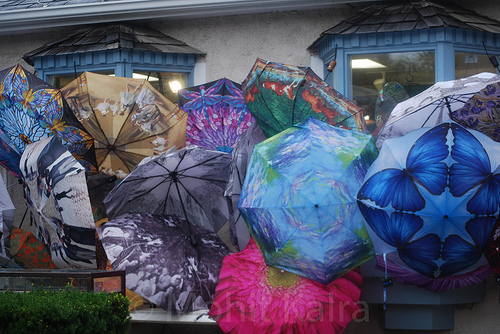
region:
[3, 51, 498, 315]
these are umbrellas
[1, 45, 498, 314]
the umbrellas are all open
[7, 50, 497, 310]
a pile of umbrellas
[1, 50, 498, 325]
the umbrellas are colorful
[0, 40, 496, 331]
the umbrellas have patterns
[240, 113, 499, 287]
these umbrellas are blue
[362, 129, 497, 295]
this umbrella has butterflies on it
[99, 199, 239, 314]
this umbrella has an image of a singer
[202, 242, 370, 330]
this umbrella looks like pink flower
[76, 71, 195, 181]
this umbrella has the image of people dancing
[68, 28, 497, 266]
many umbrellas are opened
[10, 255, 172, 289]
a glass case is underneath the umbrella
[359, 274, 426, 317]
the umbrellas are open on the ledge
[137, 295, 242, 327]
the ledge is white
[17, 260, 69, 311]
a bush is below the glass case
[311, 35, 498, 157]
windows are above the umbrellas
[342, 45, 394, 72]
lights are on in the building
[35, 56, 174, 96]
the paint is blue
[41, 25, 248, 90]
the roofs are arched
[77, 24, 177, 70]
the top is painted black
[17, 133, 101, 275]
black and white umbrella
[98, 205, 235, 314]
purple and white umbrella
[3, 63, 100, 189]
black yellow and blue umbrella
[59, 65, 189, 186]
brown umbrella with human figures on it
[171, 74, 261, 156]
purple blue and black umbrella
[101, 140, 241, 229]
inside view of a black and white umbrella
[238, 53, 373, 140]
green and red umbrella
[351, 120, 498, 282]
light blue umbrella with dark blue motifs on it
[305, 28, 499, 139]
window with blue frame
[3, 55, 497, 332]
a bunch of open umbrellas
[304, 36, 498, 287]
a window behind umbrella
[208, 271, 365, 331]
the umbrella is pink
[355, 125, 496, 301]
the umbrella is blue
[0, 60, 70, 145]
the umbrella is blue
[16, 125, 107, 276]
the umbrella is black and gray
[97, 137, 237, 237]
the umbrella is black and gray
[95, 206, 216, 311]
the umbrella is black and gray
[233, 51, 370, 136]
a multicolor umbrella upside down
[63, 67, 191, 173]
umbrella is color brown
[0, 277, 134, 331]
grass is color green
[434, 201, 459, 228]
black dot on umbrella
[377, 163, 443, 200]
blue butterfly on umbrella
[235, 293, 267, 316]
pink top of umbrella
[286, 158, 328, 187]
multicolor top of umbrella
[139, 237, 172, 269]
purple and white umbrella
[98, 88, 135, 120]
brown and white umbrella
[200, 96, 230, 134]
pink and blue umbrella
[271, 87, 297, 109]
red and green umbrella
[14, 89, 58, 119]
blue and gold umbrella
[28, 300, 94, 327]
green bushes next to umbrellas